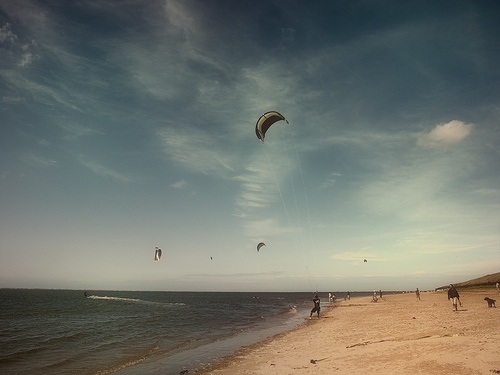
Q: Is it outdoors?
A: Yes, it is outdoors.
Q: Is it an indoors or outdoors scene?
A: It is outdoors.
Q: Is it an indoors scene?
A: No, it is outdoors.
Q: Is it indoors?
A: No, it is outdoors.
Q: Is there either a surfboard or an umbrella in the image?
A: No, there are no surfboards or umbrellas.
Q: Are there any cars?
A: No, there are no cars.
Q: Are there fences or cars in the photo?
A: No, there are no cars or fences.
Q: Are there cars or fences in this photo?
A: No, there are no cars or fences.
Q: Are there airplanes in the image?
A: No, there are no airplanes.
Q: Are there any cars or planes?
A: No, there are no planes or cars.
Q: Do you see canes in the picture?
A: No, there are no canes.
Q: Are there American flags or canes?
A: No, there are no canes or American flags.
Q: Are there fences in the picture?
A: No, there are no fences.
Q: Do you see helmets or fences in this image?
A: No, there are no fences or helmets.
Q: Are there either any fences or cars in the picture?
A: No, there are no cars or fences.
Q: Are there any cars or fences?
A: No, there are no cars or fences.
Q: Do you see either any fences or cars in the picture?
A: No, there are no cars or fences.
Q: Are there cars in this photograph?
A: No, there are no cars.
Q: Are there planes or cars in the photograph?
A: No, there are no cars or planes.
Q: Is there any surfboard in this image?
A: No, there are no surfboards.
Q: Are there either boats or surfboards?
A: No, there are no surfboards or boats.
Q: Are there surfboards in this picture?
A: No, there are no surfboards.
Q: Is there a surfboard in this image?
A: No, there are no surfboards.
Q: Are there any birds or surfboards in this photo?
A: No, there are no surfboards or birds.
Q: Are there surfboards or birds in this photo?
A: No, there are no surfboards or birds.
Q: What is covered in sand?
A: The shore is covered in sand.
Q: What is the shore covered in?
A: The shore is covered in sand.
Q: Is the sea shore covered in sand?
A: Yes, the sea shore is covered in sand.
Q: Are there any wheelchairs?
A: No, there are no wheelchairs.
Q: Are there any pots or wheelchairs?
A: No, there are no wheelchairs or pots.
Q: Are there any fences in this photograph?
A: No, there are no fences.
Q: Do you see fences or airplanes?
A: No, there are no fences or airplanes.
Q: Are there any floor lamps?
A: No, there are no floor lamps.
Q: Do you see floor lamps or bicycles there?
A: No, there are no floor lamps or bicycles.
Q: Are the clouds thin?
A: Yes, the clouds are thin.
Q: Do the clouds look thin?
A: Yes, the clouds are thin.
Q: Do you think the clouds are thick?
A: No, the clouds are thin.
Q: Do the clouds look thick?
A: No, the clouds are thin.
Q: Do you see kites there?
A: Yes, there is a kite.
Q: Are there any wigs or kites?
A: Yes, there is a kite.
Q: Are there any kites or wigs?
A: Yes, there is a kite.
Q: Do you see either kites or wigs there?
A: Yes, there is a kite.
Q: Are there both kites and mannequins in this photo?
A: No, there is a kite but no mannequins.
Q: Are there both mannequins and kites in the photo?
A: No, there is a kite but no mannequins.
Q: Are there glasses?
A: No, there are no glasses.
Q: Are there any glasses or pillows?
A: No, there are no glasses or pillows.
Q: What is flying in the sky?
A: The kite is flying in the sky.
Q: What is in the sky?
A: The kite is in the sky.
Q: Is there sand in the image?
A: Yes, there is sand.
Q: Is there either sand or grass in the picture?
A: Yes, there is sand.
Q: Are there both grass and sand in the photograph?
A: No, there is sand but no grass.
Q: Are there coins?
A: No, there are no coins.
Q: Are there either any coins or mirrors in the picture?
A: No, there are no coins or mirrors.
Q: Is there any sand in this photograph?
A: Yes, there is sand.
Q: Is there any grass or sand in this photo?
A: Yes, there is sand.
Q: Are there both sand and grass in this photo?
A: No, there is sand but no grass.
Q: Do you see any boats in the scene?
A: No, there are no boats.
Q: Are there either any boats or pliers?
A: No, there are no boats or pliers.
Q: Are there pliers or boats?
A: No, there are no boats or pliers.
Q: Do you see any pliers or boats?
A: No, there are no boats or pliers.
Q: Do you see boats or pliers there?
A: No, there are no boats or pliers.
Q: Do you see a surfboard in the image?
A: No, there are no surfboards.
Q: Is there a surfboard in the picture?
A: No, there are no surfboards.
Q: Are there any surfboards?
A: No, there are no surfboards.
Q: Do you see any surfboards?
A: No, there are no surfboards.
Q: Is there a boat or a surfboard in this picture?
A: No, there are no surfboards or boats.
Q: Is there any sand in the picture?
A: Yes, there is sand.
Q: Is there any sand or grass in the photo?
A: Yes, there is sand.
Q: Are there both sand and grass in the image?
A: No, there is sand but no grass.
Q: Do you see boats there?
A: No, there are no boats.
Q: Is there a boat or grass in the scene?
A: No, there are no boats or grass.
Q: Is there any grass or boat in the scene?
A: No, there are no boats or grass.